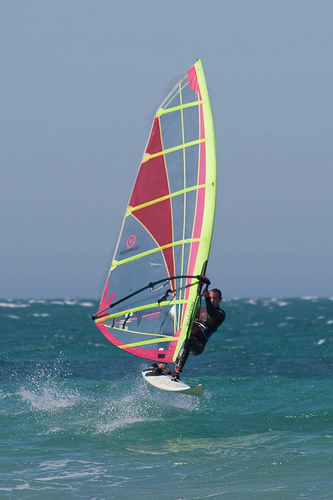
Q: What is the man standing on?
A: Surfboard.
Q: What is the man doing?
A: Windsurfing.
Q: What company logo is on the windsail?
A: Target.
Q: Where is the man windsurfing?
A: In the ocean.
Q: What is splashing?
A: Clear water.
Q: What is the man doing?
A: Windsurfing.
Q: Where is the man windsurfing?
A: In the ocean.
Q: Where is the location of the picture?
A: On the ocean.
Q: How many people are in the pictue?
A: 1.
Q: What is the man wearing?
A: A black wetsuit.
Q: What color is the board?
A: White.